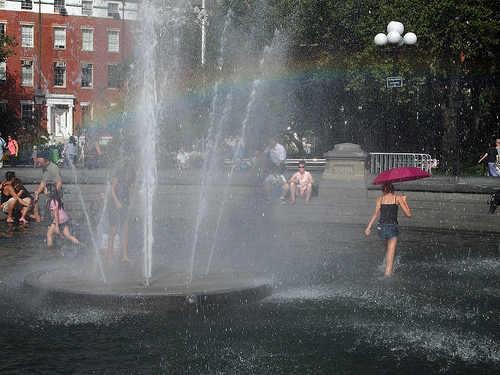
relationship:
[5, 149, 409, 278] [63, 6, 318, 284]
people are playing in water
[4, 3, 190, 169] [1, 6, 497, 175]
building in background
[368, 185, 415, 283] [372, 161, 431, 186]
woman holding an umbrella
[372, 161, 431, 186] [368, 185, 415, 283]
umbrella of woman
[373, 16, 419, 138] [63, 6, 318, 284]
light to right of water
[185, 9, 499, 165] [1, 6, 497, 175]
trees in background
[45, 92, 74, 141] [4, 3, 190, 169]
entry way for building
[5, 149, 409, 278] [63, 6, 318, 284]
people are enjoying water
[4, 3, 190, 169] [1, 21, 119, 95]
building has windows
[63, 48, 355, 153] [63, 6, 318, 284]
rainbow reflection in water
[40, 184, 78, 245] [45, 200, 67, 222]
girl wearing pink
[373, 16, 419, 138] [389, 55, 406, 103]
light on a pole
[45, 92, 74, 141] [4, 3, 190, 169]
entry way on building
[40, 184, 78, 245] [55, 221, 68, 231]
girl wearing shorts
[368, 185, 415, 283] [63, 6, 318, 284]
woman walking in water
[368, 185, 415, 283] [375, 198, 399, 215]
woman wearing tank top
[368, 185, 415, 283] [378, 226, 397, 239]
woman wearing shorts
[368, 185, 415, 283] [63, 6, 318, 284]
woman playing in water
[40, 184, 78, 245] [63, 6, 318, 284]
girl playing in water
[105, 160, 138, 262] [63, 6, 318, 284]
person playing in water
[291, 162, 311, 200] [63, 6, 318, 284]
person sitting by water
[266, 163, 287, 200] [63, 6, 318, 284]
person sitting by water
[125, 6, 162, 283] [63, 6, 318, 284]
stream of water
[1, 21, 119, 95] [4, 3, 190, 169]
windows of building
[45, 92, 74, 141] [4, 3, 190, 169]
entry way of a building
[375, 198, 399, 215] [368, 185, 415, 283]
tank top of woman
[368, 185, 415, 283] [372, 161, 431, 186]
woman walking with an umbrella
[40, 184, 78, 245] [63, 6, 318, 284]
girl in water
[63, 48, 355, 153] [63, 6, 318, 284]
rainbow reflection over water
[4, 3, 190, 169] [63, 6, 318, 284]
building behind water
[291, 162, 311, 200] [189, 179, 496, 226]
person on steps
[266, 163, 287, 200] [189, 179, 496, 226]
person on steps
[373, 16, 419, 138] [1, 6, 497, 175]
light in background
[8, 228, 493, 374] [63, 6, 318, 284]
pool of water